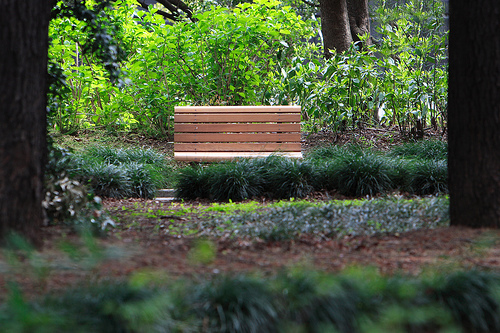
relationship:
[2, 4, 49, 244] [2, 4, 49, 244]
trunk of trunk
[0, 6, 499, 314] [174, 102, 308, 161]
forest has bench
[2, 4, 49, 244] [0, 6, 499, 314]
trunk in forest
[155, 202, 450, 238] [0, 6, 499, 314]
flowers in forest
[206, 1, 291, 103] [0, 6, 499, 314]
plants in forest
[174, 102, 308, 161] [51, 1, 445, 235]
bench behind plants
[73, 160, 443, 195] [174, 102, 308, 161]
plants in front of bench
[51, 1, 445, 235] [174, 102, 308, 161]
plants behind bench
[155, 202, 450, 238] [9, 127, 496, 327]
flowers on ground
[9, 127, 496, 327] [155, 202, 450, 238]
ground has flowers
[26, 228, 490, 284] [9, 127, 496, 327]
dirt on ground.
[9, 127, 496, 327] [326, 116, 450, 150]
ground has sticks.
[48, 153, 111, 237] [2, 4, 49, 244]
leaves at base of trunk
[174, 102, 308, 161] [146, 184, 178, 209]
bench by steps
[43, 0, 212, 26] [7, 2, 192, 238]
branch of tree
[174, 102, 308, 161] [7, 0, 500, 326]
bench in forest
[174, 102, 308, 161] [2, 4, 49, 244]
bench between each trunk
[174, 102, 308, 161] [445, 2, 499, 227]
bench between each trunk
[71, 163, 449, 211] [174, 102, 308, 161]
bushes in front of bench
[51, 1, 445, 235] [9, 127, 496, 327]
plants on ground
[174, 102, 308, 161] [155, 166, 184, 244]
bench behind path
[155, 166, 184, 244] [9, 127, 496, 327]
path on ground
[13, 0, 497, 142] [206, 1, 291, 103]
background has plants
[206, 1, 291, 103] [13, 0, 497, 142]
plants in background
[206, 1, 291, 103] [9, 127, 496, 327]
plants on ground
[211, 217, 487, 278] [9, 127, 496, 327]
leaves on ground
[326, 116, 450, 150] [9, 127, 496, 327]
branches on ground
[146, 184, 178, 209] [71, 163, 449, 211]
steps between bushes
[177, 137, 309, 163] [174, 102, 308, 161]
seat on bench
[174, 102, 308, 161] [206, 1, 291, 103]
bench between plants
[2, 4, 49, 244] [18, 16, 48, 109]
trunk has lines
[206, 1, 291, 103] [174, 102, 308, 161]
plants behind bench